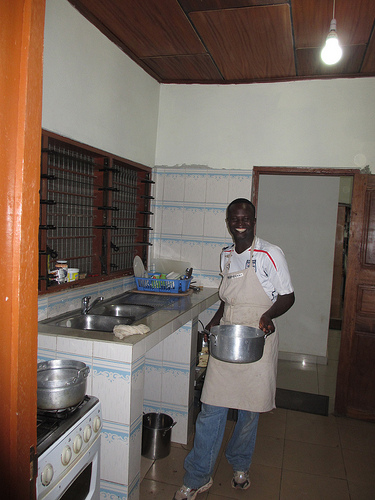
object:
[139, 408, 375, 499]
floor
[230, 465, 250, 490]
shoe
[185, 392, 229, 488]
leg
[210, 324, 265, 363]
pan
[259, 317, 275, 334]
hand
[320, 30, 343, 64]
lightbulb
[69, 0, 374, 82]
ceiling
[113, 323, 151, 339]
towel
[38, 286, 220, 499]
counter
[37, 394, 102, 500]
stove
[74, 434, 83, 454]
knob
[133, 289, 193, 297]
tray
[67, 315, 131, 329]
sink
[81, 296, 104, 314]
faucet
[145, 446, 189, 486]
rug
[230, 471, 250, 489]
foot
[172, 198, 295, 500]
cook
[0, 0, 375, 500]
kitchen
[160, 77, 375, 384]
wall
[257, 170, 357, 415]
doorway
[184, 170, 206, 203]
tiles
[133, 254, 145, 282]
plate